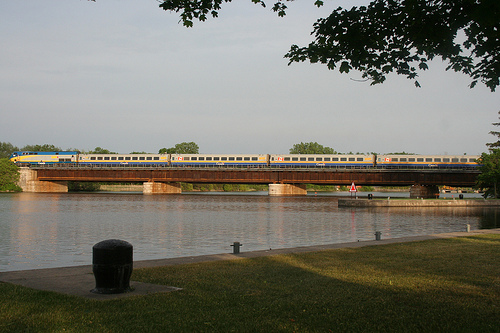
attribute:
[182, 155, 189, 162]
passenger window — passenger window, passenger train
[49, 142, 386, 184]
train — passenger window, passenger train